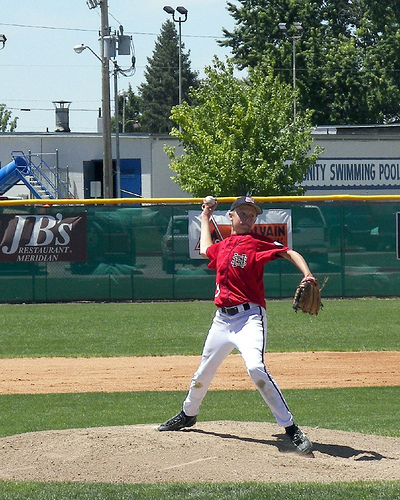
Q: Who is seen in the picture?
A: A young boy playing baseball.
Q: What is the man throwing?
A: A baseball.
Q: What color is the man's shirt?
A: Red.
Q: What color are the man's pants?
A: White.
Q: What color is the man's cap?
A: Black.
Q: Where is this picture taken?
A: A baseball field.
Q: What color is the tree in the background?
A: Green.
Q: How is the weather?
A: Sunny.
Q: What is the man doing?
A: Pitching.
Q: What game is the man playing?
A: Baseball.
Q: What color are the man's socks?
A: Black.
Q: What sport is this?
A: Baseball.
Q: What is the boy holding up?
A: A baseball.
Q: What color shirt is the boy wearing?
A: Red.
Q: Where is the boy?
A: On a baseball field.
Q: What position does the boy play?
A: Pitcher.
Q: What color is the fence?
A: Green.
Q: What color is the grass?
A: Green.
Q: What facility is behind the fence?
A: Swimming pool.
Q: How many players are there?
A: One.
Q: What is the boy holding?
A: A baseball.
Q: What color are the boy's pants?
A: White.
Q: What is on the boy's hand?
A: A baseball glove.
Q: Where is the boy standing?
A: The pitcher's mound.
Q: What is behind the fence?
A: A tree.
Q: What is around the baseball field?
A: A fence.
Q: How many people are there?
A: One.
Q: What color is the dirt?
A: Brown.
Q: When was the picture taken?
A: Daytime.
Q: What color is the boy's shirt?
A: Red.